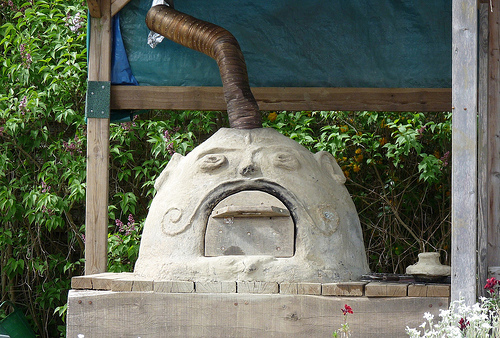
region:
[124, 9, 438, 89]
green cover on exhibit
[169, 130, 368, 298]
white clay for furnace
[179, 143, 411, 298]
face shape for furnace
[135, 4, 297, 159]
brown pipe extended from furnace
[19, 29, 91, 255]
green leaves on trees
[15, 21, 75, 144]
purple flowers on trees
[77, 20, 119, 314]
wood frame is light brown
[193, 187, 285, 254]
grey door on furnace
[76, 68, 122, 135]
green bracket on wood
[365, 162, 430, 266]
thin branches on trees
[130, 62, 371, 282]
an oven in the shape of a head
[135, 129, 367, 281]
a face sculpted on an outdoor oven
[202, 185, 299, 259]
door to outdoor oven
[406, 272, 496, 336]
white and burgandy flowers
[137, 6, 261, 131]
vent for oven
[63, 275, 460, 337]
table oven sits on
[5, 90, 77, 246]
part of a lilac bush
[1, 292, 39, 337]
green bucket with a handle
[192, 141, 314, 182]
eyes on an outdoor oven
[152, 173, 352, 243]
mustache sculpted on an outdoor oven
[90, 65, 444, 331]
LARGE OUTDOOR OVEN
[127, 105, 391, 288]
OVEN HAS FACE CARVED ON IT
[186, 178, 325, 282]
MOUTH ON OVENS FACE IS OVEN DOOR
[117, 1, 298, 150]
EXHAUST PIPE ON TOP OF OVEN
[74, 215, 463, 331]
OVEN SITS ON WOODEN BOARDS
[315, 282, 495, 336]
WHITE AND RED FLOWERS GROWING NEAR OVEN BASE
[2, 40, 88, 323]
HEAVY FOLIAGE IS IN BACKGROUND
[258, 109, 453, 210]
FRUIT TREES IN FOLIAGE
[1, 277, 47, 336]
GREEN URN TO LEFT OF OVEN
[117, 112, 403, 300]
OVEN IS COMPOSED OF CLAY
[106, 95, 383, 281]
clay wood-fired oven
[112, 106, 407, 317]
outdoor oven with face design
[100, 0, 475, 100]
blue tarp roof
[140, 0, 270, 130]
brown oven smoke stack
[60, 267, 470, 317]
counter made of wooden planks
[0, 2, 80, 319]
tree with purple flowers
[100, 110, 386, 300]
outdoor wood-fired oven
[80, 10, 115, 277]
light wooden post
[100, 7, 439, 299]
outdoor oven under a blue tarp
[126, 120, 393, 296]
oven with face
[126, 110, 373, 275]
A large outdoor oven or furnace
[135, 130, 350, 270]
Oven or furnace shaped like a head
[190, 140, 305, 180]
Head has two eyes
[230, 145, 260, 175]
Head has a nose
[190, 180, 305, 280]
The head has a mouth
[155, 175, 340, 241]
The head has a mustache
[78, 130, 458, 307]
Head sitting on a shelf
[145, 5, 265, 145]
A vent coming out of top of head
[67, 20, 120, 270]
A wooden post with green metal clamp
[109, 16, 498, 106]
A blue tarp on back